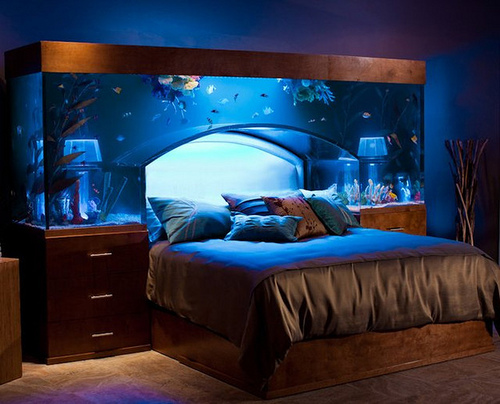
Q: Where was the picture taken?
A: It was taken at the bedroom.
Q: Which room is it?
A: It is a bedroom.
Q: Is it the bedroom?
A: Yes, it is the bedroom.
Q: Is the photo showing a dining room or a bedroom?
A: It is showing a bedroom.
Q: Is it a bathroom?
A: No, it is a bedroom.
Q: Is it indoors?
A: Yes, it is indoors.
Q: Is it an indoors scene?
A: Yes, it is indoors.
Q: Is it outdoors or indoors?
A: It is indoors.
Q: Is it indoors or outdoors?
A: It is indoors.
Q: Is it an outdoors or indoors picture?
A: It is indoors.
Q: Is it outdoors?
A: No, it is indoors.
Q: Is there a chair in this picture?
A: No, there are no chairs.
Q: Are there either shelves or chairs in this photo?
A: No, there are no chairs or shelves.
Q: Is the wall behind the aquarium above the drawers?
A: Yes, the wall is behind the aquarium.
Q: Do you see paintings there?
A: No, there are no paintings.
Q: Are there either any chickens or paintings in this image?
A: No, there are no paintings or chickens.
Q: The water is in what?
A: The water is in the aquarium.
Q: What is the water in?
A: The water is in the aquarium.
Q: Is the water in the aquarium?
A: Yes, the water is in the aquarium.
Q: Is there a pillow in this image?
A: Yes, there is a pillow.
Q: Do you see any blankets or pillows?
A: Yes, there is a pillow.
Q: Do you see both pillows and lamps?
A: Yes, there are both a pillow and a lamp.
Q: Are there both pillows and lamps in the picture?
A: Yes, there are both a pillow and a lamp.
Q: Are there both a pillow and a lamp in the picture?
A: Yes, there are both a pillow and a lamp.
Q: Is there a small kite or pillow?
A: Yes, there is a small pillow.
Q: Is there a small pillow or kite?
A: Yes, there is a small pillow.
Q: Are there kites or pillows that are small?
A: Yes, the pillow is small.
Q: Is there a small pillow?
A: Yes, there is a small pillow.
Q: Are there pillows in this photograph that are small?
A: Yes, there is a pillow that is small.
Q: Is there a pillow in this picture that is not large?
A: Yes, there is a small pillow.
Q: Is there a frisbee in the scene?
A: No, there are no frisbees.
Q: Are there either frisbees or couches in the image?
A: No, there are no frisbees or couches.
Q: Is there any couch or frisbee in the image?
A: No, there are no frisbees or couches.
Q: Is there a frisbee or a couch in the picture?
A: No, there are no frisbees or couches.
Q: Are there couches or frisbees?
A: No, there are no frisbees or couches.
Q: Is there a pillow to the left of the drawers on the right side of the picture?
A: Yes, there is a pillow to the left of the drawers.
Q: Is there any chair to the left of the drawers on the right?
A: No, there is a pillow to the left of the drawers.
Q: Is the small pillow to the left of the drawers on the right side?
A: Yes, the pillow is to the left of the drawers.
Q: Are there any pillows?
A: Yes, there is a pillow.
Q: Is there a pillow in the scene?
A: Yes, there is a pillow.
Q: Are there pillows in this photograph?
A: Yes, there is a pillow.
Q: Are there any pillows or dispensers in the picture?
A: Yes, there is a pillow.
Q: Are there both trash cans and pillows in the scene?
A: No, there is a pillow but no trash cans.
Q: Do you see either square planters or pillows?
A: Yes, there is a square pillow.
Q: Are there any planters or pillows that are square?
A: Yes, the pillow is square.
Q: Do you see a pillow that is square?
A: Yes, there is a square pillow.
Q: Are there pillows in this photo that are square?
A: Yes, there is a pillow that is square.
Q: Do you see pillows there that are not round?
A: Yes, there is a square pillow.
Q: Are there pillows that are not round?
A: Yes, there is a square pillow.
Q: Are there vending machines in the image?
A: No, there are no vending machines.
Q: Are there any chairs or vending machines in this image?
A: No, there are no vending machines or chairs.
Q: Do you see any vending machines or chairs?
A: No, there are no vending machines or chairs.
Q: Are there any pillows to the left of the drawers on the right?
A: Yes, there is a pillow to the left of the drawers.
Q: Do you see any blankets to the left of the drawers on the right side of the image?
A: No, there is a pillow to the left of the drawers.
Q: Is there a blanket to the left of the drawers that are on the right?
A: No, there is a pillow to the left of the drawers.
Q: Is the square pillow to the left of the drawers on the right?
A: Yes, the pillow is to the left of the drawers.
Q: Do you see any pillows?
A: Yes, there is a pillow.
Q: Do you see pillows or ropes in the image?
A: Yes, there is a pillow.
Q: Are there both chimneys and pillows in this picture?
A: No, there is a pillow but no chimneys.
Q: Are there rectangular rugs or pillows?
A: Yes, there is a rectangular pillow.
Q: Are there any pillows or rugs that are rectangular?
A: Yes, the pillow is rectangular.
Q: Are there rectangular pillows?
A: Yes, there is a rectangular pillow.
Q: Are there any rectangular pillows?
A: Yes, there is a rectangular pillow.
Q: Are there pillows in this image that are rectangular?
A: Yes, there is a pillow that is rectangular.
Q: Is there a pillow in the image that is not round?
A: Yes, there is a rectangular pillow.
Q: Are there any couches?
A: No, there are no couches.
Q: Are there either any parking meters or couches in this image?
A: No, there are no couches or parking meters.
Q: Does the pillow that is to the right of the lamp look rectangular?
A: Yes, the pillow is rectangular.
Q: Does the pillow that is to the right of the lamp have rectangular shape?
A: Yes, the pillow is rectangular.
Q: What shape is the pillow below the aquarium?
A: The pillow is rectangular.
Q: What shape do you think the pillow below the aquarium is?
A: The pillow is rectangular.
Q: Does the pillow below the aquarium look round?
A: No, the pillow is rectangular.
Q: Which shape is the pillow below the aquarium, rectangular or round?
A: The pillow is rectangular.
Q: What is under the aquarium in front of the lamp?
A: The pillow is under the aquarium.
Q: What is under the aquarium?
A: The pillow is under the aquarium.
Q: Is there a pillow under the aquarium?
A: Yes, there is a pillow under the aquarium.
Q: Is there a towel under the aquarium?
A: No, there is a pillow under the aquarium.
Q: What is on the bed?
A: The pillow is on the bed.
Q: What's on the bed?
A: The pillow is on the bed.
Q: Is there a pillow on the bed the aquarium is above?
A: Yes, there is a pillow on the bed.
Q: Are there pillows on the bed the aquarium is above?
A: Yes, there is a pillow on the bed.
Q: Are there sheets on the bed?
A: No, there is a pillow on the bed.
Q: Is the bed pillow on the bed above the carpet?
A: Yes, the pillow is on the bed.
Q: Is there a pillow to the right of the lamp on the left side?
A: Yes, there is a pillow to the right of the lamp.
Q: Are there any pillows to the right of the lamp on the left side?
A: Yes, there is a pillow to the right of the lamp.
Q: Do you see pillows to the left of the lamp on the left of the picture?
A: No, the pillow is to the right of the lamp.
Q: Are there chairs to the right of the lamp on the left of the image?
A: No, there is a pillow to the right of the lamp.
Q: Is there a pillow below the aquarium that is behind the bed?
A: Yes, there is a pillow below the aquarium.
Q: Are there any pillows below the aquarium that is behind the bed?
A: Yes, there is a pillow below the aquarium.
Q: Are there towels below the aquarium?
A: No, there is a pillow below the aquarium.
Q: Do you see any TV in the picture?
A: No, there are no televisions.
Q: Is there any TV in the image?
A: No, there are no televisions.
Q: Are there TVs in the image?
A: No, there are no tvs.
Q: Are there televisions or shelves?
A: No, there are no televisions or shelves.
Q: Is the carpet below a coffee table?
A: No, the carpet is below the bed.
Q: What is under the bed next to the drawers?
A: The carpet is under the bed.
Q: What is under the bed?
A: The carpet is under the bed.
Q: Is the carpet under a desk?
A: No, the carpet is under a bed.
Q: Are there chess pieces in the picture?
A: No, there are no chess pieces.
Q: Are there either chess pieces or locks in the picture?
A: No, there are no chess pieces or locks.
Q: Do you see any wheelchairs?
A: No, there are no wheelchairs.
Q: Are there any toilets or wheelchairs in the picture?
A: No, there are no wheelchairs or toilets.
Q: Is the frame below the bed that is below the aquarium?
A: Yes, the frame is below the bed.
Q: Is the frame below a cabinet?
A: No, the frame is below the bed.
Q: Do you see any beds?
A: Yes, there is a bed.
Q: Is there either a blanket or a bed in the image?
A: Yes, there is a bed.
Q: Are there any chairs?
A: No, there are no chairs.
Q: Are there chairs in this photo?
A: No, there are no chairs.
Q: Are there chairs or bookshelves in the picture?
A: No, there are no chairs or bookshelves.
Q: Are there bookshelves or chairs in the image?
A: No, there are no chairs or bookshelves.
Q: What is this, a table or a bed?
A: This is a bed.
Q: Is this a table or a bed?
A: This is a bed.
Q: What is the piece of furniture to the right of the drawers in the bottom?
A: The piece of furniture is a bed.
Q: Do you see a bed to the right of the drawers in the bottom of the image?
A: Yes, there is a bed to the right of the drawers.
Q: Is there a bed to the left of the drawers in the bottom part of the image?
A: No, the bed is to the right of the drawers.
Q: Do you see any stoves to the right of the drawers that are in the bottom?
A: No, there is a bed to the right of the drawers.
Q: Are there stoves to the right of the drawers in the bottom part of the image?
A: No, there is a bed to the right of the drawers.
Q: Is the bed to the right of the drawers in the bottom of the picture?
A: Yes, the bed is to the right of the drawers.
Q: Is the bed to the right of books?
A: No, the bed is to the right of the drawers.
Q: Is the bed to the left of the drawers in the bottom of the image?
A: No, the bed is to the right of the drawers.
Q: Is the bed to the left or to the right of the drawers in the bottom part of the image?
A: The bed is to the right of the drawers.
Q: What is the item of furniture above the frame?
A: The piece of furniture is a bed.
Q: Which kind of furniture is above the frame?
A: The piece of furniture is a bed.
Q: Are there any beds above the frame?
A: Yes, there is a bed above the frame.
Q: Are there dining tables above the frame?
A: No, there is a bed above the frame.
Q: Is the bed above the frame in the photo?
A: Yes, the bed is above the frame.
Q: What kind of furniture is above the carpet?
A: The piece of furniture is a bed.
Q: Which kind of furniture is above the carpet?
A: The piece of furniture is a bed.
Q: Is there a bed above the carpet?
A: Yes, there is a bed above the carpet.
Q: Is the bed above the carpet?
A: Yes, the bed is above the carpet.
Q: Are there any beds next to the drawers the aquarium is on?
A: Yes, there is a bed next to the drawers.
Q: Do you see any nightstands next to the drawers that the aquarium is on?
A: No, there is a bed next to the drawers.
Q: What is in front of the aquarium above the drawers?
A: The bed is in front of the aquarium.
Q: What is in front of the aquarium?
A: The bed is in front of the aquarium.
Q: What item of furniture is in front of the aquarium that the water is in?
A: The piece of furniture is a bed.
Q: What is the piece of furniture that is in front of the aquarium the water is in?
A: The piece of furniture is a bed.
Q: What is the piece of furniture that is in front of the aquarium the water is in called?
A: The piece of furniture is a bed.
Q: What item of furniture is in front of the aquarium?
A: The piece of furniture is a bed.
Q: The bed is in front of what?
A: The bed is in front of the aquarium.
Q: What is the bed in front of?
A: The bed is in front of the aquarium.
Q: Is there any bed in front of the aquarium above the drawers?
A: Yes, there is a bed in front of the aquarium.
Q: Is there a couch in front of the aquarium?
A: No, there is a bed in front of the aquarium.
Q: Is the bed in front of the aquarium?
A: Yes, the bed is in front of the aquarium.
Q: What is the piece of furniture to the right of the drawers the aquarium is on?
A: The piece of furniture is a bed.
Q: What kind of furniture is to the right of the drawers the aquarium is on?
A: The piece of furniture is a bed.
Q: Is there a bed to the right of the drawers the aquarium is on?
A: Yes, there is a bed to the right of the drawers.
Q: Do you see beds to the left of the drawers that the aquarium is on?
A: No, the bed is to the right of the drawers.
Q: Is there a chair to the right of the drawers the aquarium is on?
A: No, there is a bed to the right of the drawers.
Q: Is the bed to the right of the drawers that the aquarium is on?
A: Yes, the bed is to the right of the drawers.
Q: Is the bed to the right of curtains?
A: No, the bed is to the right of the drawers.